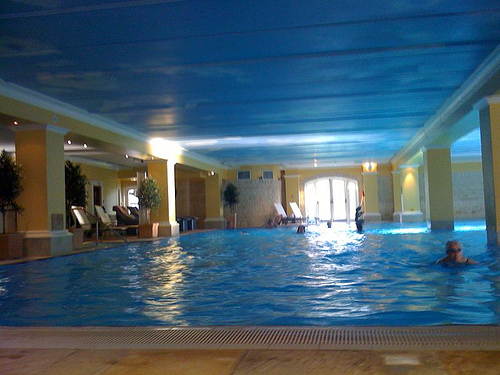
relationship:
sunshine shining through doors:
[293, 190, 369, 255] [299, 173, 358, 222]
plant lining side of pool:
[221, 182, 241, 214] [0, 221, 500, 326]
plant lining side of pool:
[137, 177, 163, 224] [0, 221, 500, 326]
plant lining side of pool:
[64, 159, 89, 228] [0, 221, 500, 326]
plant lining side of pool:
[0, 149, 26, 217] [0, 221, 500, 326]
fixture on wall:
[403, 170, 411, 181] [393, 164, 420, 214]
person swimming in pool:
[435, 241, 477, 265] [108, 173, 455, 344]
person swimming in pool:
[272, 213, 339, 254] [108, 173, 455, 344]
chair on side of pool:
[69, 191, 124, 276] [163, 210, 377, 310]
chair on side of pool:
[272, 201, 290, 230] [163, 210, 377, 310]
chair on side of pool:
[290, 196, 314, 230] [163, 210, 377, 310]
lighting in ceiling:
[12, 120, 17, 125] [0, 2, 500, 169]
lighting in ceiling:
[82, 142, 87, 147] [0, 2, 500, 169]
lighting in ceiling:
[123, 152, 131, 160] [0, 2, 500, 169]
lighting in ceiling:
[66, 138, 72, 143] [0, 2, 500, 169]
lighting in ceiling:
[208, 170, 214, 175] [0, 2, 500, 169]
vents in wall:
[236, 163, 279, 190] [221, 166, 288, 228]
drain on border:
[0, 313, 500, 351] [8, 321, 486, 370]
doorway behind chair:
[84, 179, 121, 244] [63, 182, 124, 258]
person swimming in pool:
[435, 241, 477, 265] [0, 222, 500, 328]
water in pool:
[228, 228, 379, 328] [0, 222, 500, 328]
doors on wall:
[290, 167, 357, 224] [219, 155, 433, 226]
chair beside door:
[288, 201, 309, 223] [287, 154, 447, 276]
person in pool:
[389, 232, 474, 272] [0, 222, 500, 328]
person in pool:
[435, 241, 477, 265] [0, 222, 500, 328]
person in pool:
[311, 206, 352, 240] [0, 222, 500, 328]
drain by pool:
[232, 313, 424, 370] [124, 223, 392, 301]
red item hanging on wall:
[361, 185, 367, 200] [282, 166, 389, 216]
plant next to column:
[2, 152, 27, 211] [145, 159, 178, 232]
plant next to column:
[65, 160, 90, 211] [18, 122, 71, 248]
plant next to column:
[136, 174, 161, 223] [201, 169, 225, 224]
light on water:
[138, 233, 202, 323] [219, 240, 316, 298]